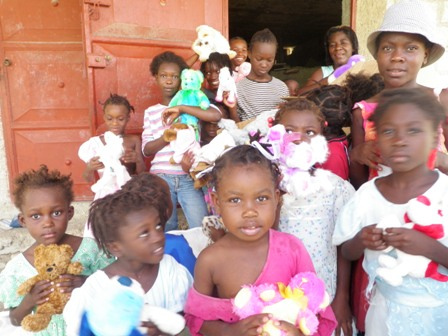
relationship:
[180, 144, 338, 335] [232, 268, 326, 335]
child holding animal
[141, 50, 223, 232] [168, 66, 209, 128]
child holding bear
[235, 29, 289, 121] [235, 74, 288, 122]
child in gray shirt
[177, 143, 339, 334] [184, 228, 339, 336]
child wear t shirt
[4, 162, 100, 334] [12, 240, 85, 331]
child holding bear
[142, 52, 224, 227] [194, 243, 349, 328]
child holding bear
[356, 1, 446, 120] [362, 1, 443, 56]
person wearing hat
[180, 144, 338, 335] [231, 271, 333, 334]
child holding animal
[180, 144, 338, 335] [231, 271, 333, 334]
child clutching animal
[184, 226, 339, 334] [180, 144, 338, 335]
t shirt on child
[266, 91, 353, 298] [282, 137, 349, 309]
girl holding teddy bear